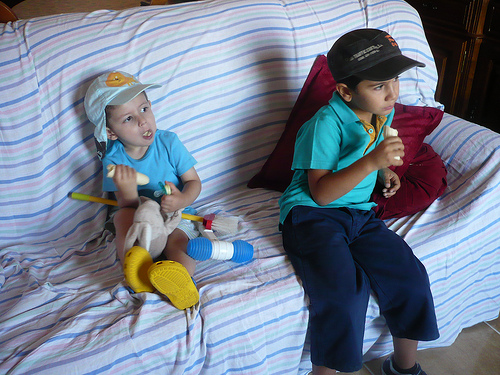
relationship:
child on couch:
[82, 67, 202, 313] [3, 3, 499, 374]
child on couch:
[277, 26, 440, 372] [3, 3, 499, 374]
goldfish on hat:
[107, 70, 138, 90] [81, 68, 164, 163]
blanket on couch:
[2, 6, 499, 375] [3, 3, 499, 374]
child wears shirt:
[277, 26, 440, 372] [274, 84, 397, 230]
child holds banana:
[277, 26, 440, 372] [382, 123, 403, 166]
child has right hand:
[277, 26, 440, 372] [377, 137, 406, 169]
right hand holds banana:
[377, 137, 406, 169] [382, 123, 403, 166]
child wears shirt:
[82, 67, 202, 313] [100, 128, 200, 218]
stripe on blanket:
[374, 19, 421, 30] [2, 6, 499, 375]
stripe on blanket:
[366, 3, 414, 11] [2, 6, 499, 375]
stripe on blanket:
[401, 42, 430, 52] [2, 6, 499, 375]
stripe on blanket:
[463, 135, 499, 167] [2, 6, 499, 375]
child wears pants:
[277, 26, 440, 372] [281, 199, 439, 373]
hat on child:
[81, 68, 164, 163] [82, 67, 202, 313]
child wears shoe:
[82, 67, 202, 313] [147, 261, 201, 310]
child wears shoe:
[82, 67, 202, 313] [123, 245, 159, 296]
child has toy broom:
[82, 67, 202, 313] [70, 193, 240, 236]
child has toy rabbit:
[82, 67, 202, 313] [123, 199, 182, 262]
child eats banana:
[82, 67, 202, 313] [105, 163, 151, 187]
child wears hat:
[277, 26, 440, 372] [324, 25, 426, 93]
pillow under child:
[243, 53, 443, 200] [277, 26, 440, 372]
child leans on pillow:
[277, 26, 440, 372] [243, 53, 443, 200]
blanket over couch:
[2, 6, 499, 375] [3, 3, 499, 374]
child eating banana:
[82, 67, 202, 313] [105, 163, 151, 187]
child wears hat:
[82, 67, 202, 313] [81, 68, 164, 163]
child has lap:
[82, 67, 202, 313] [103, 198, 204, 247]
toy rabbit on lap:
[123, 199, 182, 262] [103, 198, 204, 247]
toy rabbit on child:
[123, 199, 182, 262] [82, 67, 202, 313]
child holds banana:
[82, 67, 202, 313] [105, 163, 151, 187]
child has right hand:
[82, 67, 202, 313] [113, 162, 142, 189]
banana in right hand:
[105, 163, 151, 187] [113, 162, 142, 189]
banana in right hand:
[382, 123, 403, 166] [377, 137, 406, 169]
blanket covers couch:
[2, 6, 499, 375] [3, 3, 499, 374]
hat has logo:
[324, 25, 426, 93] [383, 32, 398, 50]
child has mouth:
[82, 67, 202, 313] [139, 127, 154, 143]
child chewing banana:
[82, 67, 202, 313] [105, 163, 151, 187]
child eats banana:
[277, 26, 440, 372] [382, 123, 403, 166]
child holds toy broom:
[82, 67, 202, 313] [70, 193, 240, 236]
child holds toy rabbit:
[82, 67, 202, 313] [123, 199, 182, 262]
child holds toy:
[82, 67, 202, 313] [185, 208, 256, 264]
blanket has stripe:
[2, 6, 499, 375] [401, 42, 430, 52]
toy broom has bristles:
[70, 193, 240, 236] [212, 213, 240, 237]